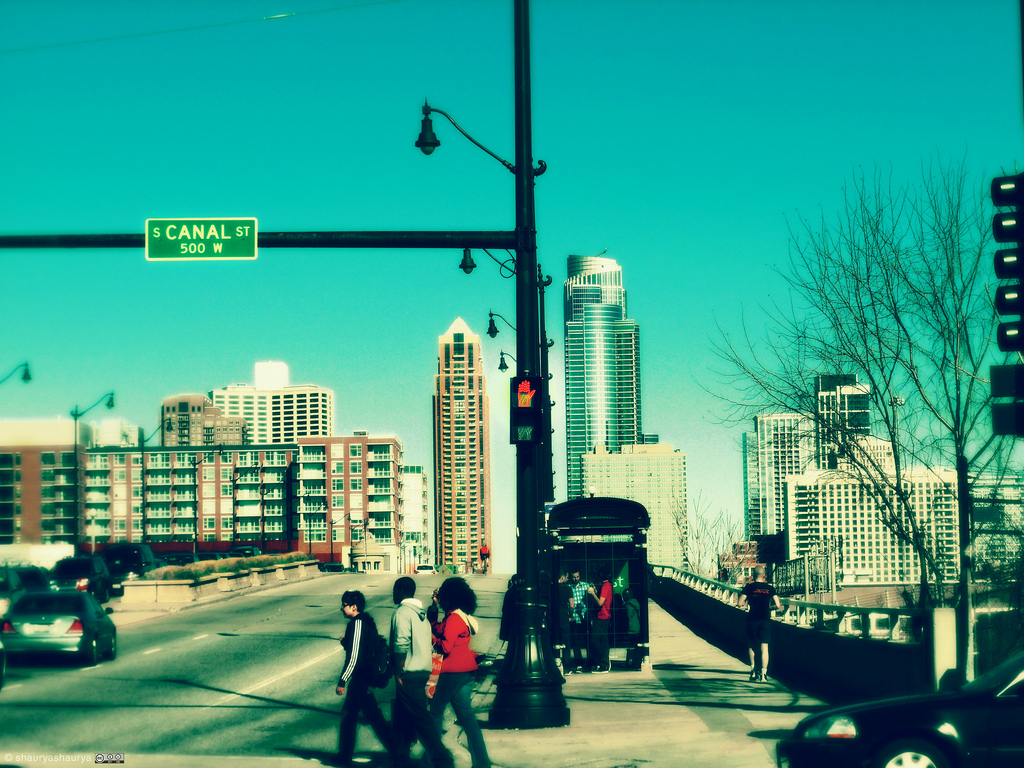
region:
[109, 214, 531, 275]
There is a sign on the pole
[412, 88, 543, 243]
The light is hanging on the pole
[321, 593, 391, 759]
The woman has on a black jacket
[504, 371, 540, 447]
There is a red hand on the sign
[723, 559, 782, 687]
The man is walking on the side walk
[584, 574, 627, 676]
The man has on a red shirt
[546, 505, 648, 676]
Three people at the bus stop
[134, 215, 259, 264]
Green street sign with white letters.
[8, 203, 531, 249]
Black street sign pole across the road.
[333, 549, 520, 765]
Three people walking across the road.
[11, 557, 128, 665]
Silver car parked on the side of tthe car.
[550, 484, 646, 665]
Black bus stop stand on the side of the road.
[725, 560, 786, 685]
Man running across the sidewalk.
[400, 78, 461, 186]
Black lamp shade on the side of the pole.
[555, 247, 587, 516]
Silver building looking over the others.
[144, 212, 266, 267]
green street sign on the post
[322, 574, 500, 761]
people are crossing the street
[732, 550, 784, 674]
person walking down the sidewalk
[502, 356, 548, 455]
pedestrian crossing sign on don't walk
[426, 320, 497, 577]
tall building down the road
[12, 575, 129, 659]
car driving down the road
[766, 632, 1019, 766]
car stopped at the light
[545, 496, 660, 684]
shelter at the bus stop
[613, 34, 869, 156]
blue grey sky above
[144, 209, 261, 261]
A green street sign on a pole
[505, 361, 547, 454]
A crosswalk sign on a pole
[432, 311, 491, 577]
A tall building in the city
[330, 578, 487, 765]
People crossing the street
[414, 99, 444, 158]
A light on a pole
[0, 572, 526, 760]
A street in a city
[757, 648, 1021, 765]
A black car in the city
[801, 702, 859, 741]
A headlight on a car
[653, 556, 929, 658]
Railing on a bridge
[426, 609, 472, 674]
woman wearing a red coat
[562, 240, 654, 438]
tall silver building behind the bus stop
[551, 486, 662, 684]
bus stop shelter on the side of the street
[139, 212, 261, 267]
green street sign on a post above the road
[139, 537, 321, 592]
flowers growing along the side of the road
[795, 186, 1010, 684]
bare tree at the street corner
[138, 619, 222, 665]
white lines painted in the road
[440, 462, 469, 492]
a window on the building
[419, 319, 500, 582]
a tall brown building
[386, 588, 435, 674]
a man's gray hooded shirt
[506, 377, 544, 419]
a pedestrian sign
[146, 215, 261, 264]
a green and white street sign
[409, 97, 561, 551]
a tall black street light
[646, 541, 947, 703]
the side of a bridge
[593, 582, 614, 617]
a man's short sleeve red shirt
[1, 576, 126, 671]
the back of a car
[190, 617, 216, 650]
a white street marking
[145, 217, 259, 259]
a green and white sign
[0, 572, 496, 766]
people crossing the street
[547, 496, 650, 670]
people standing under a bus stop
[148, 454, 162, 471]
glass window on building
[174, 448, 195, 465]
glass window on building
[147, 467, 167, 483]
glass window on building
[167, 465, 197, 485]
glass window on building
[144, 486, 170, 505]
glass window on building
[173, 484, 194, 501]
glass window on building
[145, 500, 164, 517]
glass window on building